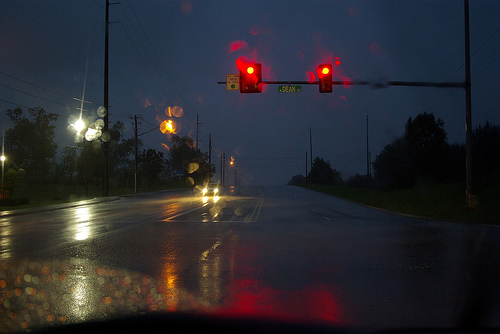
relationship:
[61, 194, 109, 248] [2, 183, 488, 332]
light reflected on road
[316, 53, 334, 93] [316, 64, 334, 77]
traffic light has red light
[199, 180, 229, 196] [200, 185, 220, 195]
car has headlights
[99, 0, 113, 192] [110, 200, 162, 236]
powerline pole on road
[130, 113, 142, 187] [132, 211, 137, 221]
powerline pole on road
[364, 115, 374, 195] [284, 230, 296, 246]
powerline pole on road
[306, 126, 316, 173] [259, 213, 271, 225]
powerline pole on road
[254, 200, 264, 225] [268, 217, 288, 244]
lines in street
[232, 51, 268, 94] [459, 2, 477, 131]
traffic light on pole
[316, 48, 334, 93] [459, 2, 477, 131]
traffic light on pole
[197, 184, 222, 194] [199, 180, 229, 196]
headlights on car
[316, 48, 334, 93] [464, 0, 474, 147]
traffic light on pole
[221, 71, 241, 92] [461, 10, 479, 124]
sign on pole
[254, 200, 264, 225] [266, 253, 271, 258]
lines on road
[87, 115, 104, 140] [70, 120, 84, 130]
glare on lights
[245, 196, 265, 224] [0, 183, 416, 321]
lines on road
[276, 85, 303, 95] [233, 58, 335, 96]
road sign between traffic lights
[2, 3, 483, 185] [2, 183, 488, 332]
sky hanging over road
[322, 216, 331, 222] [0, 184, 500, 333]
line painted on road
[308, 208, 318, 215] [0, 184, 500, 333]
line painted on road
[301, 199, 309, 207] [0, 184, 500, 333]
line painted on road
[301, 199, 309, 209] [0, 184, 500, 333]
line painted on road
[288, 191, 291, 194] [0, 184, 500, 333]
line painted on road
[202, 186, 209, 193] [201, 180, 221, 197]
headlight shining on car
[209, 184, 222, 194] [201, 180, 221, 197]
headlights shining on car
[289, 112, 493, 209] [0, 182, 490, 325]
trees lining streets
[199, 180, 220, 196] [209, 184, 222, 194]
car with headlights